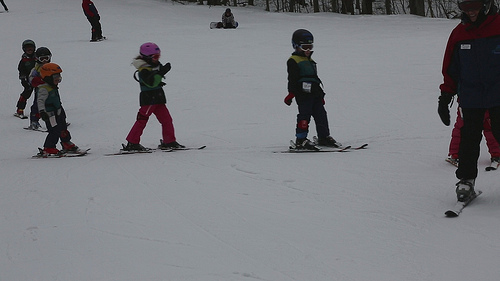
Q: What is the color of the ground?
A: White.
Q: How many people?
A: 9.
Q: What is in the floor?
A: Snow.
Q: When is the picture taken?
A: Daytime.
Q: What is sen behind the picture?
A: Trees.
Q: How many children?
A: 5.